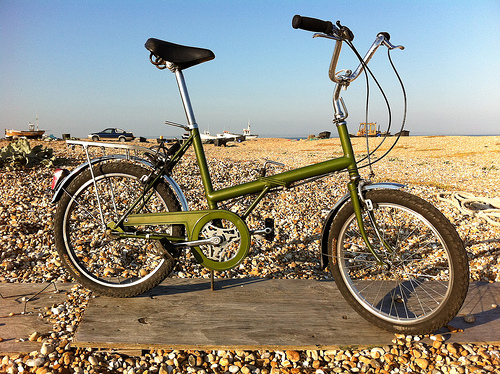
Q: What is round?
A: Tires.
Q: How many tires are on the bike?
A: Two.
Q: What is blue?
A: Sky.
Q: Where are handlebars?
A: On a bicycle.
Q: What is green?
A: Bicycle.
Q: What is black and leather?
A: Bicycle seat.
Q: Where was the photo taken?
A: At a gravel lot.